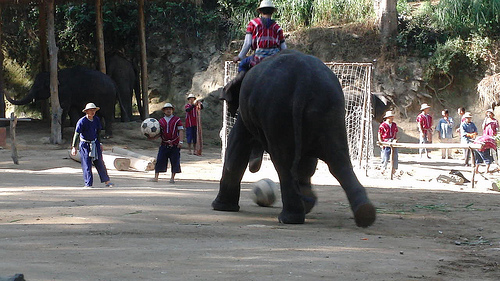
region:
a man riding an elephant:
[207, 0, 382, 233]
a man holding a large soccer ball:
[138, 95, 192, 189]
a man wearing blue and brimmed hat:
[64, 101, 118, 192]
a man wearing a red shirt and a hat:
[371, 102, 406, 174]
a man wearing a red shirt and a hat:
[413, 101, 440, 162]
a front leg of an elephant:
[211, 132, 246, 213]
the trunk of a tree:
[40, 10, 67, 146]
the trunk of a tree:
[131, 6, 154, 118]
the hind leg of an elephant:
[321, 125, 385, 227]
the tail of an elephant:
[284, 92, 321, 197]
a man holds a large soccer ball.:
[138, 116, 161, 144]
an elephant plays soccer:
[212, 54, 380, 231]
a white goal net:
[223, 60, 370, 174]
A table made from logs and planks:
[383, 137, 478, 186]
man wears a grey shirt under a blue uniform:
[72, 120, 115, 187]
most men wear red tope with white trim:
[154, 117, 177, 184]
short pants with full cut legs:
[155, 142, 184, 172]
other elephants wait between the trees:
[43, 51, 139, 131]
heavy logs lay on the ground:
[70, 142, 158, 174]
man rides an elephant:
[233, 0, 288, 76]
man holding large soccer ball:
[139, 105, 183, 184]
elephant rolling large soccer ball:
[215, 55, 380, 227]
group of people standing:
[379, 103, 499, 165]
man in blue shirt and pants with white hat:
[72, 99, 109, 184]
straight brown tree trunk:
[46, 5, 61, 147]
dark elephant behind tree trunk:
[3, 68, 114, 136]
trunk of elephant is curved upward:
[2, 77, 34, 113]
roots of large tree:
[376, 50, 454, 107]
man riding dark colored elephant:
[215, 0, 377, 230]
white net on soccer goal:
[218, 53, 377, 179]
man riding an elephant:
[224, 0, 307, 109]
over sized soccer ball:
[249, 174, 271, 201]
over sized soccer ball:
[145, 121, 162, 140]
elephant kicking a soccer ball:
[213, 81, 311, 215]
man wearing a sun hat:
[79, 98, 99, 120]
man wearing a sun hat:
[161, 102, 172, 114]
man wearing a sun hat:
[180, 89, 202, 110]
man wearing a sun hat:
[382, 102, 396, 132]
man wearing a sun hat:
[416, 99, 429, 120]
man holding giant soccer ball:
[138, 97, 193, 178]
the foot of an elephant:
[203, 168, 243, 218]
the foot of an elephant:
[279, 192, 306, 227]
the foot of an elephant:
[346, 197, 378, 234]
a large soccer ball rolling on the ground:
[248, 177, 279, 209]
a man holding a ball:
[139, 102, 185, 184]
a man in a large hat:
[78, 101, 103, 112]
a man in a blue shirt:
[69, 116, 104, 146]